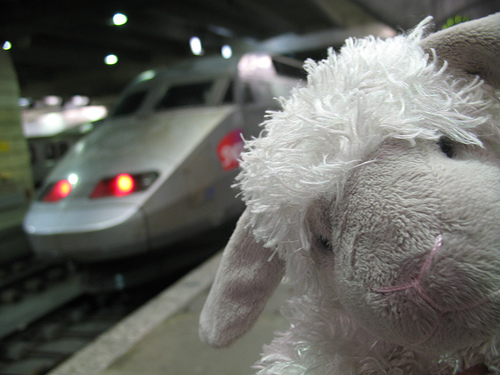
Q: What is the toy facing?
A: The camera.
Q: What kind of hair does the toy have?
A: Long strands.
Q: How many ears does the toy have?
A: Two.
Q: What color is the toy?
A: White.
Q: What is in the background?
A: Train.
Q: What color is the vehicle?
A: Gray.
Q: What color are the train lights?
A: Red.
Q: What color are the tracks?
A: Gray.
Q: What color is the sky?
A: Black.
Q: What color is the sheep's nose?
A: Pink.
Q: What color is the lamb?
A: White.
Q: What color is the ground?
A: Gray.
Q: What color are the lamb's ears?
A: Gray.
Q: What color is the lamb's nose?
A: Pink.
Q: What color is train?
A: Steel and grey.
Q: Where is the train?
A: Left side of picture.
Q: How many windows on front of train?
A: Two.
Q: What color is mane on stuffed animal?
A: White.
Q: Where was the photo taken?
A: A subway.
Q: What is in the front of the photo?
A: A toy lamb.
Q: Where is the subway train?
A: On the tracks.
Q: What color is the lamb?
A: White.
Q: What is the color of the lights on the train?
A: Red.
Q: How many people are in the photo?
A: None.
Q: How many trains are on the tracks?
A: One.